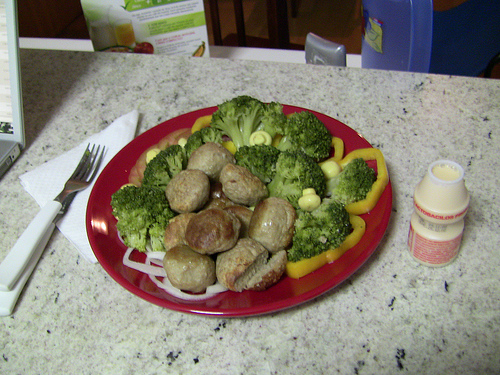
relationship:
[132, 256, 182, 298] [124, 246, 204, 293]
slices of onions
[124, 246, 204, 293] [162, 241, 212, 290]
onions under meatball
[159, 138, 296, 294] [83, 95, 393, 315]
meat balls on plate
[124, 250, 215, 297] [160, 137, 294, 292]
onions under meatballs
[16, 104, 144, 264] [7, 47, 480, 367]
napkin on table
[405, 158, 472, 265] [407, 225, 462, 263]
jug has writing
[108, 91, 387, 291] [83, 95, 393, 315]
food on plate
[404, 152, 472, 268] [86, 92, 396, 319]
drink for a meal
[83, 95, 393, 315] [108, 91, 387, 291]
plate filled with food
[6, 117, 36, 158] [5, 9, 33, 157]
corner of a laptop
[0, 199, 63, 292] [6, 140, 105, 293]
handle for forks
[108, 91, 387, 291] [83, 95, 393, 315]
food lying on top of plate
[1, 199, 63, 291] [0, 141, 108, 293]
handle attached to utensils